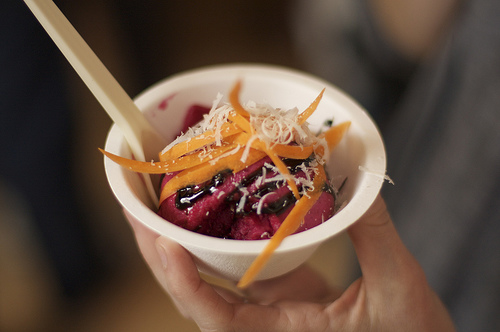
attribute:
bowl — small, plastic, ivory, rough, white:
[102, 62, 386, 282]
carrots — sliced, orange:
[99, 79, 349, 286]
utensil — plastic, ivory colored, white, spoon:
[23, 1, 169, 211]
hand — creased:
[122, 201, 457, 332]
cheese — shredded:
[161, 95, 298, 155]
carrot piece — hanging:
[236, 165, 326, 287]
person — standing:
[290, 0, 498, 332]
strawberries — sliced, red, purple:
[184, 154, 267, 230]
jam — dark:
[176, 156, 312, 211]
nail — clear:
[154, 243, 168, 271]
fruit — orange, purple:
[98, 79, 348, 286]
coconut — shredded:
[162, 93, 330, 192]